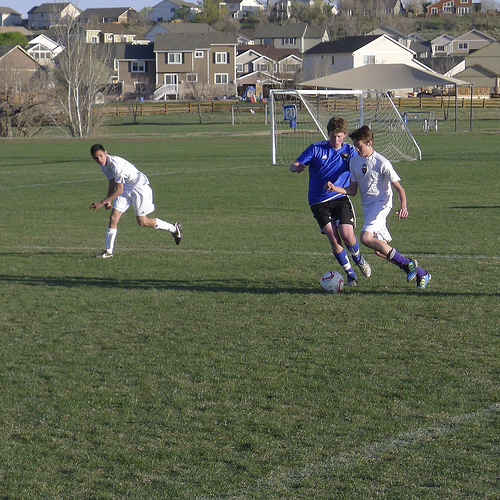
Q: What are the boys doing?
A: Playing soccer.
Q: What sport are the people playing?
A: Soccer.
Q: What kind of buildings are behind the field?
A: Houses.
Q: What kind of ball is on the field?
A: Soccer.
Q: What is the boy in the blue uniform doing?
A: Kicking a soccer ball.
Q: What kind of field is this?
A: A soccer field.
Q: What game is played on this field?
A: Soccer.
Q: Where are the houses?
A: Behind the soccer field.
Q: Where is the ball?
A: By the blue player.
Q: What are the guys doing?
A: Playing soccer.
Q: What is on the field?
A: A net.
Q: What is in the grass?
A: White paint.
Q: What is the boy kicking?
A: Ball.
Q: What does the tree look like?
A: No leaves.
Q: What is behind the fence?
A: Houses.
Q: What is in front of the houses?
A: A tent.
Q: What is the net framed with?
A: PVC.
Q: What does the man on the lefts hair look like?
A: Short.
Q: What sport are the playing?
A: Soccer.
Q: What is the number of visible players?
A: Three.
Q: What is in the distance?
A: Houses.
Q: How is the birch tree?
A: Leafless.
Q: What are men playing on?
A: Grass.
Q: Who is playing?
A: Men.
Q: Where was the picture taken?
A: Field.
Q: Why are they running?
A: Playing.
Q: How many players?
A: Three.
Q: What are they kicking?
A: Ball.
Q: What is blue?
A: Shirt.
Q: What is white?
A: Shorts.